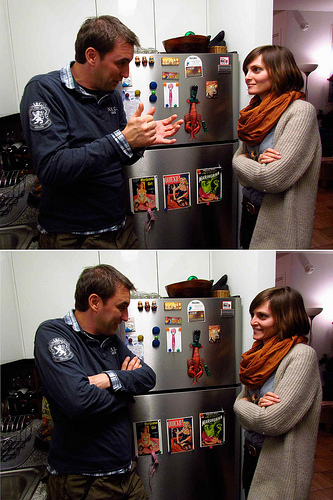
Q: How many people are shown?
A: 2.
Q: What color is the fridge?
A: Silver.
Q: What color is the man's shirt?
A: Blue.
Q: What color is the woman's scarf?
A: Orange.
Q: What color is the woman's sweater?
A: Tan.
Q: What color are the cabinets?
A: White.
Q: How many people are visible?
A: Two.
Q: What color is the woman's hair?
A: Brown.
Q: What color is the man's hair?
A: Brown.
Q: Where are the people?
A: In a kitchen.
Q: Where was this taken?
A: Kitchen.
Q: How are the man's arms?
A: Crossed.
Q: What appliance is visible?
A: Refrigerator.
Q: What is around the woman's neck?
A: Scarf.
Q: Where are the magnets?
A: On the refrigerator.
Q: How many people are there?
A: 2.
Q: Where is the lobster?
A: On the fridge.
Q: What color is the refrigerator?
A: Silver.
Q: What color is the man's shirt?
A: Blue.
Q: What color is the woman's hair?
A: Brown.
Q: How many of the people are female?
A: 1.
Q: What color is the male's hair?
A: Brown.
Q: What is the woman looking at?
A: The guy.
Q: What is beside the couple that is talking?
A: Refrigerator.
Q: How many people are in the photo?
A: Two.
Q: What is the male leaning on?
A: The counter.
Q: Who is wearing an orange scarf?
A: The female.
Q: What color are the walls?
A: White.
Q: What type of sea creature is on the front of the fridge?
A: Lobster.